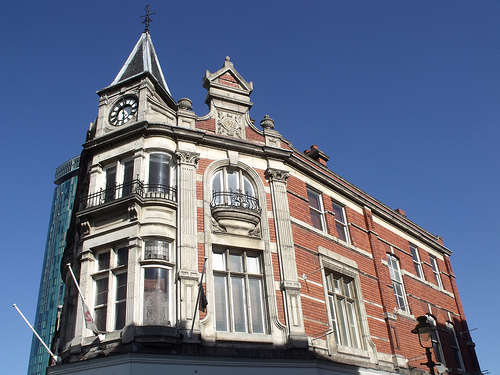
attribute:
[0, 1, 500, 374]
sky — clear, blue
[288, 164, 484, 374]
wall — brick, red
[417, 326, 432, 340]
light — off, old style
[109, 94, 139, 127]
clock — black, white, here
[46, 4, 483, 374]
building — tall, brown, white, brick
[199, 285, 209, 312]
flag — white, hanging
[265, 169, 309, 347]
spire — decorative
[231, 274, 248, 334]
window — long, large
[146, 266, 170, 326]
window — fancy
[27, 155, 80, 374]
building — tall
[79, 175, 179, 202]
railing — black